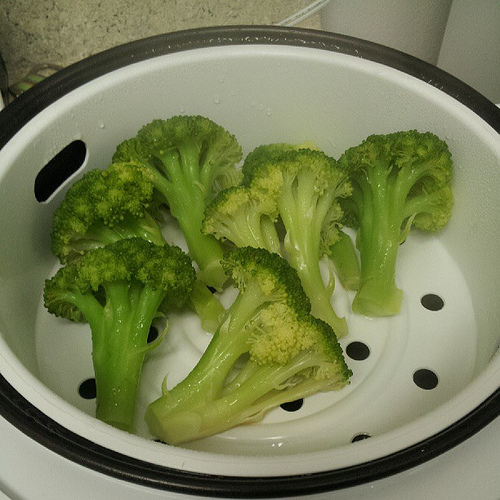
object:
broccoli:
[49, 234, 181, 416]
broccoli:
[332, 114, 458, 324]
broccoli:
[144, 241, 364, 448]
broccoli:
[103, 100, 250, 286]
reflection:
[7, 0, 498, 150]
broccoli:
[199, 142, 353, 338]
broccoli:
[112, 113, 241, 290]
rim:
[163, 22, 401, 61]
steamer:
[25, 25, 499, 455]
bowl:
[6, 42, 498, 482]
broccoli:
[38, 115, 455, 445]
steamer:
[0, 25, 497, 498]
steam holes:
[341, 287, 448, 364]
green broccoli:
[156, 230, 349, 455]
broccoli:
[200, 148, 349, 259]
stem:
[348, 208, 409, 320]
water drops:
[63, 101, 115, 134]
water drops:
[206, 86, 283, 119]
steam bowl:
[0, 26, 498, 496]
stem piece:
[90, 293, 147, 427]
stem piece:
[348, 184, 406, 313]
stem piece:
[172, 192, 230, 288]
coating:
[0, 43, 498, 374]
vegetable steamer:
[0, 25, 500, 495]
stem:
[85, 287, 155, 425]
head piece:
[38, 237, 198, 319]